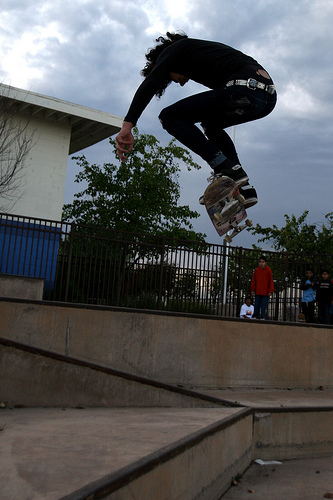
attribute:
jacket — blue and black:
[299, 288, 315, 300]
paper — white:
[250, 451, 289, 469]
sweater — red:
[251, 264, 273, 293]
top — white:
[239, 303, 254, 317]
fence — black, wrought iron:
[3, 209, 332, 329]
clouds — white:
[0, 0, 332, 250]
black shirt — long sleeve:
[124, 37, 275, 85]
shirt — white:
[130, 17, 267, 99]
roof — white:
[1, 80, 126, 152]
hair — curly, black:
[149, 32, 177, 80]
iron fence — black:
[7, 220, 329, 325]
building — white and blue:
[0, 109, 62, 288]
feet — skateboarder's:
[195, 169, 263, 200]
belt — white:
[234, 81, 278, 91]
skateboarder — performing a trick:
[109, 32, 281, 241]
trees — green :
[47, 132, 207, 309]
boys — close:
[251, 262, 330, 324]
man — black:
[112, 30, 278, 207]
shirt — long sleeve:
[122, 37, 278, 125]